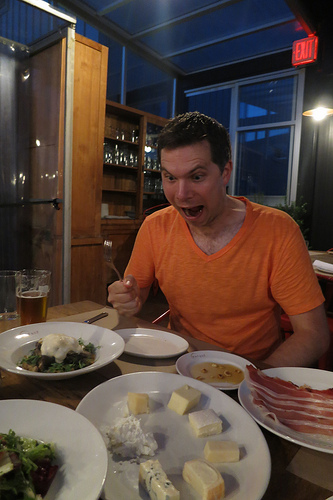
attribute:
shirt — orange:
[117, 205, 325, 349]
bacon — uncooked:
[248, 366, 331, 427]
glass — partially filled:
[12, 267, 50, 324]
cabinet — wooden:
[104, 99, 170, 287]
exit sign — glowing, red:
[288, 32, 317, 66]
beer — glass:
[10, 250, 56, 317]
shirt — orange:
[127, 198, 321, 348]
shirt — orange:
[109, 188, 322, 352]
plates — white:
[88, 364, 233, 489]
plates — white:
[232, 365, 330, 453]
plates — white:
[182, 343, 264, 409]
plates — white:
[19, 310, 104, 380]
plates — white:
[117, 324, 214, 382]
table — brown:
[38, 284, 190, 437]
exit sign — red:
[279, 29, 330, 73]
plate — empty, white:
[115, 320, 192, 375]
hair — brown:
[154, 105, 208, 146]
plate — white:
[174, 348, 257, 390]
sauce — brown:
[188, 360, 242, 384]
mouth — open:
[174, 202, 204, 219]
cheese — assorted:
[105, 383, 241, 499]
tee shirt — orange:
[122, 195, 327, 364]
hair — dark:
[152, 109, 233, 176]